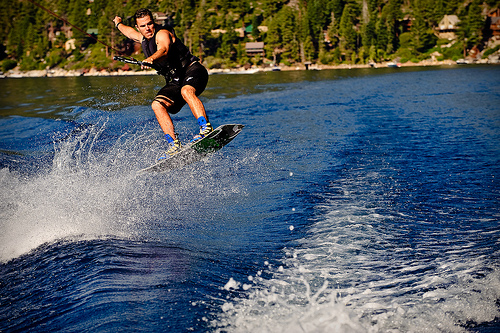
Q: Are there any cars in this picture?
A: No, there are no cars.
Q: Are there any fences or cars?
A: No, there are no cars or fences.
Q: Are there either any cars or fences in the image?
A: No, there are no cars or fences.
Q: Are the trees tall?
A: Yes, the trees are tall.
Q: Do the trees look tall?
A: Yes, the trees are tall.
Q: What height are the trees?
A: The trees are tall.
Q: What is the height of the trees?
A: The trees are tall.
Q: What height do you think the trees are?
A: The trees are tall.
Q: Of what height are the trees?
A: The trees are tall.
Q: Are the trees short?
A: No, the trees are tall.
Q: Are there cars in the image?
A: No, there are no cars.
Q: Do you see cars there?
A: No, there are no cars.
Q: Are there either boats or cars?
A: No, there are no cars or boats.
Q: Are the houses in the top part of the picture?
A: Yes, the houses are in the top of the image.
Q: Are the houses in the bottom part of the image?
A: No, the houses are in the top of the image.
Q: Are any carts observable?
A: No, there are no carts.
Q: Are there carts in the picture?
A: No, there are no carts.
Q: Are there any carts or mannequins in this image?
A: No, there are no carts or mannequins.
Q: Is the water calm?
A: Yes, the water is calm.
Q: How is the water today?
A: The water is calm.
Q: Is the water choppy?
A: No, the water is calm.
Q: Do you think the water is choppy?
A: No, the water is calm.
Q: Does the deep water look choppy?
A: No, the water is calm.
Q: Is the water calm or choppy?
A: The water is calm.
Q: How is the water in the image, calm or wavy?
A: The water is calm.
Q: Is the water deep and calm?
A: Yes, the water is deep and calm.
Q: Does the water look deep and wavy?
A: No, the water is deep but calm.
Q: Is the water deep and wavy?
A: No, the water is deep but calm.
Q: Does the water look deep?
A: Yes, the water is deep.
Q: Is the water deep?
A: Yes, the water is deep.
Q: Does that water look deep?
A: Yes, the water is deep.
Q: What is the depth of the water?
A: The water is deep.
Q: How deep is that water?
A: The water is deep.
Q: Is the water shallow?
A: No, the water is deep.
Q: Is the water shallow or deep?
A: The water is deep.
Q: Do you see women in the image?
A: No, there are no women.